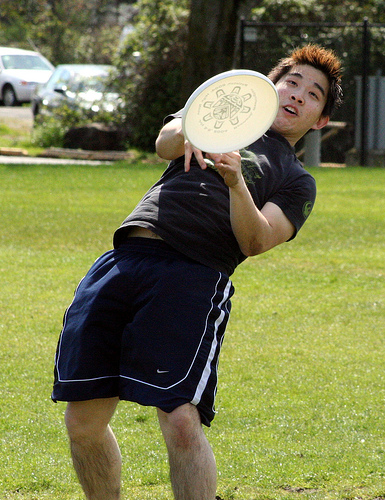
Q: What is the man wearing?
A: The man is wearing a tshirt.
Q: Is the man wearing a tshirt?
A: Yes, the man is wearing a tshirt.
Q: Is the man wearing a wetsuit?
A: No, the man is wearing a tshirt.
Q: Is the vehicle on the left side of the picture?
A: Yes, the vehicle is on the left of the image.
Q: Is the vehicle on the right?
A: No, the vehicle is on the left of the image.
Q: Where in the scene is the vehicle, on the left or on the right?
A: The vehicle is on the left of the image.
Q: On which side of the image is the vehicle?
A: The vehicle is on the left of the image.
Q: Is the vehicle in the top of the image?
A: Yes, the vehicle is in the top of the image.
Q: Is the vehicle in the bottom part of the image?
A: No, the vehicle is in the top of the image.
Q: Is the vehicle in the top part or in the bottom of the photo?
A: The vehicle is in the top of the image.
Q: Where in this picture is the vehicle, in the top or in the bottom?
A: The vehicle is in the top of the image.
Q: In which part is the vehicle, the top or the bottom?
A: The vehicle is in the top of the image.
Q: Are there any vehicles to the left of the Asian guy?
A: Yes, there is a vehicle to the left of the guy.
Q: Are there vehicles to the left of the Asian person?
A: Yes, there is a vehicle to the left of the guy.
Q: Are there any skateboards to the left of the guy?
A: No, there is a vehicle to the left of the guy.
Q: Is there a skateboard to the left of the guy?
A: No, there is a vehicle to the left of the guy.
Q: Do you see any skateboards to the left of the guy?
A: No, there is a vehicle to the left of the guy.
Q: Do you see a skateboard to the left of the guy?
A: No, there is a vehicle to the left of the guy.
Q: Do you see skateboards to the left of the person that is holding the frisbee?
A: No, there is a vehicle to the left of the guy.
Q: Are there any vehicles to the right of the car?
A: No, the vehicle is to the left of the car.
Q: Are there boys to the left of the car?
A: No, there is a vehicle to the left of the car.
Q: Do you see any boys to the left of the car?
A: No, there is a vehicle to the left of the car.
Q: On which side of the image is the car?
A: The car is on the left of the image.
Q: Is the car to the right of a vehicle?
A: Yes, the car is to the right of a vehicle.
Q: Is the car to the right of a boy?
A: No, the car is to the right of a vehicle.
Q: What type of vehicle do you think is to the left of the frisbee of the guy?
A: The vehicle is a car.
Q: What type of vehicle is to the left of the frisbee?
A: The vehicle is a car.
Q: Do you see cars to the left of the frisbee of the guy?
A: Yes, there is a car to the left of the frisbee.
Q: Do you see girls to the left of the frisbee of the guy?
A: No, there is a car to the left of the frisbee.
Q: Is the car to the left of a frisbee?
A: Yes, the car is to the left of a frisbee.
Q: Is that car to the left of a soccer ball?
A: No, the car is to the left of a frisbee.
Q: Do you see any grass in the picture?
A: Yes, there is grass.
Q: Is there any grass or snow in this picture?
A: Yes, there is grass.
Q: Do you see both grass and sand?
A: No, there is grass but no sand.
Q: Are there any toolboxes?
A: No, there are no toolboxes.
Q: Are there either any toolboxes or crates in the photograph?
A: No, there are no toolboxes or crates.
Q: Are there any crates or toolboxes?
A: No, there are no toolboxes or crates.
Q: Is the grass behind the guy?
A: Yes, the grass is behind the guy.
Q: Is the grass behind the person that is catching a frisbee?
A: Yes, the grass is behind the guy.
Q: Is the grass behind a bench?
A: No, the grass is behind the guy.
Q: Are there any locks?
A: No, there are no locks.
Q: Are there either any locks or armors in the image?
A: No, there are no locks or armors.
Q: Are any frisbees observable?
A: Yes, there is a frisbee.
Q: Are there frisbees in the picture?
A: Yes, there is a frisbee.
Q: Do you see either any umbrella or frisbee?
A: Yes, there is a frisbee.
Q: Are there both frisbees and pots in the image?
A: No, there is a frisbee but no pots.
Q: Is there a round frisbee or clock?
A: Yes, there is a round frisbee.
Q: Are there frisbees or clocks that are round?
A: Yes, the frisbee is round.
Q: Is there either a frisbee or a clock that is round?
A: Yes, the frisbee is round.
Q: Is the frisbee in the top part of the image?
A: Yes, the frisbee is in the top of the image.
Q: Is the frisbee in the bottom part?
A: No, the frisbee is in the top of the image.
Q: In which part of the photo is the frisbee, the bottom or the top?
A: The frisbee is in the top of the image.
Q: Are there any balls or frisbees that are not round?
A: No, there is a frisbee but it is round.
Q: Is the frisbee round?
A: Yes, the frisbee is round.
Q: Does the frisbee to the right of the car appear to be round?
A: Yes, the frisbee is round.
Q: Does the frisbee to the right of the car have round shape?
A: Yes, the frisbee is round.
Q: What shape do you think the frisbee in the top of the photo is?
A: The frisbee is round.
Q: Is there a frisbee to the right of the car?
A: Yes, there is a frisbee to the right of the car.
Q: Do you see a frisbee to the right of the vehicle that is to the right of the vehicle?
A: Yes, there is a frisbee to the right of the car.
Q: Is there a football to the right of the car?
A: No, there is a frisbee to the right of the car.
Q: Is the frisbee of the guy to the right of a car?
A: Yes, the frisbee is to the right of a car.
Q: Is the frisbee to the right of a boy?
A: No, the frisbee is to the right of a car.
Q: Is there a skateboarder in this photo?
A: No, there are no skateboarders.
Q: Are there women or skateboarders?
A: No, there are no skateboarders or women.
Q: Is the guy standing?
A: Yes, the guy is standing.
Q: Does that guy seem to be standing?
A: Yes, the guy is standing.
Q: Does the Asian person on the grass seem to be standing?
A: Yes, the guy is standing.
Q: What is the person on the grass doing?
A: The guy is standing.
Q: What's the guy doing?
A: The guy is standing.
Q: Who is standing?
A: The guy is standing.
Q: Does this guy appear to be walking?
A: No, the guy is standing.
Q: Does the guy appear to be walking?
A: No, the guy is standing.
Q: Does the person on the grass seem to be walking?
A: No, the guy is standing.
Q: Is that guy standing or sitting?
A: The guy is standing.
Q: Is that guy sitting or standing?
A: The guy is standing.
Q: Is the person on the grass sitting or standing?
A: The guy is standing.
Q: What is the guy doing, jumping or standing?
A: The guy is standing.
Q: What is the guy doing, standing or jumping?
A: The guy is standing.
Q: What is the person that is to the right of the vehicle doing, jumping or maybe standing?
A: The guy is standing.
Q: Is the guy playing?
A: Yes, the guy is playing.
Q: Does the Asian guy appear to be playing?
A: Yes, the guy is playing.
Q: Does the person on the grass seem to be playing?
A: Yes, the guy is playing.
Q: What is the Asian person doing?
A: The guy is playing.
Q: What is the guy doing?
A: The guy is playing.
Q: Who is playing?
A: The guy is playing.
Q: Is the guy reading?
A: No, the guy is playing.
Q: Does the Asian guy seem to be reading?
A: No, the guy is playing.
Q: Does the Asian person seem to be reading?
A: No, the guy is playing.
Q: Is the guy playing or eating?
A: The guy is playing.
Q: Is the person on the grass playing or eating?
A: The guy is playing.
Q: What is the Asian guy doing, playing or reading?
A: The guy is playing.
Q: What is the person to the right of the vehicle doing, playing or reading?
A: The guy is playing.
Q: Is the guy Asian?
A: Yes, the guy is asian.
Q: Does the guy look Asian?
A: Yes, the guy is asian.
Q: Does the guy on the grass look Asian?
A: Yes, the guy is asian.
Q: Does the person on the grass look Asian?
A: Yes, the guy is asian.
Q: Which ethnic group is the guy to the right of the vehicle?
A: The guy is asian.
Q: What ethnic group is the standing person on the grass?
A: The guy is asian.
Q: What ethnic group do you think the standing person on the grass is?
A: The guy is asian.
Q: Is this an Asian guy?
A: Yes, this is an Asian guy.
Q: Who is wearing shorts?
A: The guy is wearing shorts.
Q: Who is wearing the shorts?
A: The guy is wearing shorts.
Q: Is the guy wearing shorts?
A: Yes, the guy is wearing shorts.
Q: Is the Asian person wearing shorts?
A: Yes, the guy is wearing shorts.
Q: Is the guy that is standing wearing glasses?
A: No, the guy is wearing shorts.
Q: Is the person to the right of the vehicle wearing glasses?
A: No, the guy is wearing shorts.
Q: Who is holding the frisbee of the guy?
A: The guy is holding the frisbee.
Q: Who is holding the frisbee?
A: The guy is holding the frisbee.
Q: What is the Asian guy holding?
A: The guy is holding the frisbee.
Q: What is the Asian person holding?
A: The guy is holding the frisbee.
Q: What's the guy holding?
A: The guy is holding the frisbee.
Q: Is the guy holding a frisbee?
A: Yes, the guy is holding a frisbee.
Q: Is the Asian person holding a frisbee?
A: Yes, the guy is holding a frisbee.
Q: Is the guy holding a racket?
A: No, the guy is holding a frisbee.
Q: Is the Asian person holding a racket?
A: No, the guy is holding a frisbee.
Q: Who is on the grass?
A: The guy is on the grass.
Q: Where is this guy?
A: The guy is on the grass.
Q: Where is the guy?
A: The guy is on the grass.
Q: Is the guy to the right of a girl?
A: No, the guy is to the right of the vehicle.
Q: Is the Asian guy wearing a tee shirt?
A: Yes, the guy is wearing a tee shirt.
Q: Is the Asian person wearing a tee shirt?
A: Yes, the guy is wearing a tee shirt.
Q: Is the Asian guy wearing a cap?
A: No, the guy is wearing a tee shirt.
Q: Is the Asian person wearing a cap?
A: No, the guy is wearing a tee shirt.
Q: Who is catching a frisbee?
A: The guy is catching a frisbee.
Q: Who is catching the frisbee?
A: The guy is catching a frisbee.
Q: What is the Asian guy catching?
A: The guy is catching a frisbee.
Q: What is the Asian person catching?
A: The guy is catching a frisbee.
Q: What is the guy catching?
A: The guy is catching a frisbee.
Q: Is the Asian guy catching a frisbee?
A: Yes, the guy is catching a frisbee.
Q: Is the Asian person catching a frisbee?
A: Yes, the guy is catching a frisbee.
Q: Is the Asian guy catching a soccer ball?
A: No, the guy is catching a frisbee.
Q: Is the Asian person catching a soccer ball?
A: No, the guy is catching a frisbee.